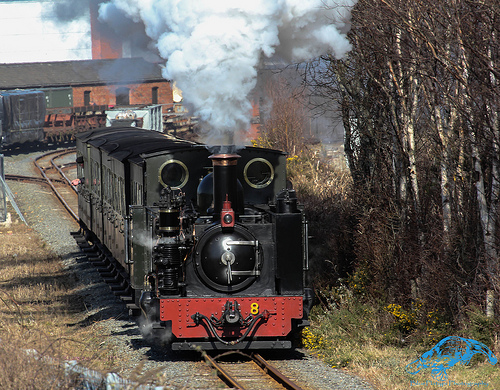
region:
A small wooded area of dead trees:
[307, 0, 499, 343]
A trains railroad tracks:
[33, 140, 302, 389]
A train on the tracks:
[75, 126, 311, 356]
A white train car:
[106, 102, 165, 129]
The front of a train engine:
[144, 145, 302, 350]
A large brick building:
[0, 57, 172, 138]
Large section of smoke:
[96, 0, 349, 150]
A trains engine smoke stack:
[210, 152, 241, 224]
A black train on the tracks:
[77, 127, 306, 348]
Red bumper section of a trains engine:
[159, 297, 306, 337]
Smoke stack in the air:
[160, 19, 254, 149]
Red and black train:
[51, 103, 306, 388]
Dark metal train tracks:
[192, 354, 290, 385]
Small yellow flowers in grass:
[385, 294, 457, 361]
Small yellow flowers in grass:
[300, 324, 331, 364]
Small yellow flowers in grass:
[334, 249, 386, 302]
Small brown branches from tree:
[455, 129, 495, 251]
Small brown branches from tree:
[430, 225, 481, 320]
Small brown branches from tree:
[383, 177, 441, 299]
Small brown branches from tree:
[340, 139, 419, 309]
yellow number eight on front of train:
[238, 296, 283, 328]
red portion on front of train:
[168, 296, 301, 338]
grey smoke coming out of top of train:
[191, 17, 271, 79]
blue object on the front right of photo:
[399, 299, 497, 380]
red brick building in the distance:
[76, 73, 150, 112]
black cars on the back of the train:
[82, 141, 139, 234]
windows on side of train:
[103, 170, 123, 200]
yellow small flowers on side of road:
[383, 296, 413, 323]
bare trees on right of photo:
[402, 57, 490, 167]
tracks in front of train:
[218, 358, 289, 385]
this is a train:
[61, 127, 288, 332]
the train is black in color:
[100, 145, 147, 224]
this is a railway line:
[177, 355, 298, 384]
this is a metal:
[212, 364, 236, 389]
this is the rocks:
[301, 363, 314, 385]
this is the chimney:
[205, 153, 238, 205]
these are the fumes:
[191, 38, 243, 110]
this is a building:
[23, 67, 90, 99]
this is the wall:
[91, 93, 116, 103]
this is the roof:
[23, 67, 78, 82]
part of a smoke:
[208, 54, 239, 96]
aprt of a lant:
[391, 246, 411, 306]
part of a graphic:
[420, 341, 449, 380]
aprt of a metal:
[224, 310, 246, 332]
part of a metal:
[222, 300, 272, 347]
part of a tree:
[403, 215, 437, 266]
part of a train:
[211, 249, 266, 335]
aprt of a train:
[224, 335, 245, 366]